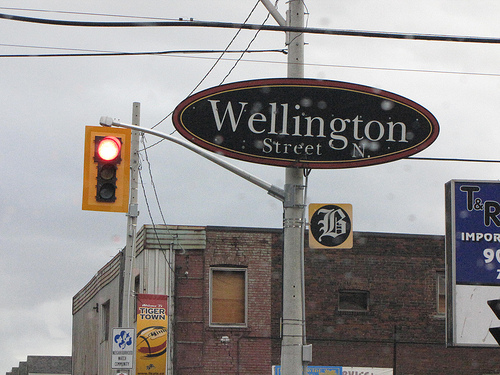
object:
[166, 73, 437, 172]
sign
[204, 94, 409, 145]
lettering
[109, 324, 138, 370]
white/blue sign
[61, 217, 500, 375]
brick building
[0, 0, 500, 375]
gray sky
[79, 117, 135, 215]
traffic signal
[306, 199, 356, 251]
black/yellow sign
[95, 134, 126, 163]
red/traffic light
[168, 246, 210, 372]
ladder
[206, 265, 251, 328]
window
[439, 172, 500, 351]
advertising sign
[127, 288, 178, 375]
advertising sign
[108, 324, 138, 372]
sign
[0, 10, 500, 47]
power lines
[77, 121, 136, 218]
stoplight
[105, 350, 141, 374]
street sign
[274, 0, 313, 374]
pole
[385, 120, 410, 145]
letter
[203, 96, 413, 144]
word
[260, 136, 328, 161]
word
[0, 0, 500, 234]
clouds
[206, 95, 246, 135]
letter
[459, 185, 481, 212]
letter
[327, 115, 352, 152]
letter